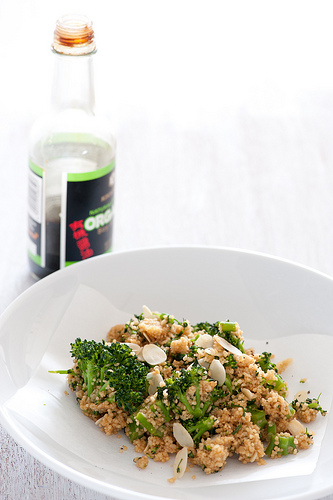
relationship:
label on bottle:
[26, 132, 115, 278] [15, 7, 124, 260]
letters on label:
[82, 212, 104, 231] [26, 132, 115, 278]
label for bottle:
[26, 132, 115, 278] [20, 16, 117, 290]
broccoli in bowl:
[69, 337, 148, 413] [1, 245, 332, 495]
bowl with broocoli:
[1, 245, 332, 495] [76, 336, 142, 406]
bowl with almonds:
[1, 245, 332, 495] [206, 356, 223, 382]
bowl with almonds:
[1, 245, 332, 495] [143, 344, 166, 360]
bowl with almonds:
[1, 245, 332, 495] [172, 421, 194, 450]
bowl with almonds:
[1, 245, 332, 495] [173, 444, 184, 475]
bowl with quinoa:
[1, 245, 332, 495] [204, 409, 259, 468]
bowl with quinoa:
[1, 245, 332, 495] [81, 392, 115, 414]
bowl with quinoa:
[1, 245, 332, 495] [263, 394, 292, 419]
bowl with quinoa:
[1, 245, 332, 495] [148, 434, 175, 459]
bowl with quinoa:
[1, 245, 332, 495] [112, 325, 136, 342]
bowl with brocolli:
[1, 245, 332, 495] [261, 345, 271, 373]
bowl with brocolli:
[1, 245, 332, 495] [131, 410, 159, 436]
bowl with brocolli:
[1, 245, 332, 495] [265, 422, 276, 455]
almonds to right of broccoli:
[116, 311, 217, 372] [69, 337, 148, 413]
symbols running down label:
[68, 221, 109, 260] [26, 132, 115, 278]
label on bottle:
[26, 132, 115, 278] [18, 22, 119, 278]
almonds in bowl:
[143, 342, 169, 367] [1, 245, 332, 495]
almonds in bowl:
[214, 336, 240, 355] [1, 245, 332, 495]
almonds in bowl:
[195, 334, 212, 348] [1, 245, 332, 495]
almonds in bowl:
[208, 359, 225, 385] [1, 245, 332, 495]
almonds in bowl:
[170, 422, 193, 447] [1, 245, 332, 495]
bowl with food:
[1, 245, 332, 495] [109, 338, 228, 451]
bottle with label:
[25, 19, 116, 282] [26, 138, 116, 268]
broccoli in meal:
[69, 337, 148, 413] [63, 302, 322, 481]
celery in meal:
[276, 433, 304, 453] [63, 302, 322, 481]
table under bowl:
[141, 161, 282, 247] [181, 251, 291, 336]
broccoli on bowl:
[91, 344, 183, 434] [1, 245, 332, 495]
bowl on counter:
[1, 245, 332, 495] [1, 1, 330, 497]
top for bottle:
[50, 15, 96, 55] [20, 16, 117, 290]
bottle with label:
[18, 19, 152, 273] [58, 165, 125, 268]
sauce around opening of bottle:
[51, 27, 97, 48] [26, 19, 111, 280]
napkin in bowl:
[1, 281, 332, 491] [1, 245, 332, 495]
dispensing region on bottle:
[51, 12, 96, 33] [20, 16, 117, 290]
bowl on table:
[1, 245, 332, 495] [30, 471, 51, 496]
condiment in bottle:
[41, 226, 68, 249] [40, 13, 115, 179]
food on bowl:
[43, 300, 330, 488] [1, 245, 332, 495]